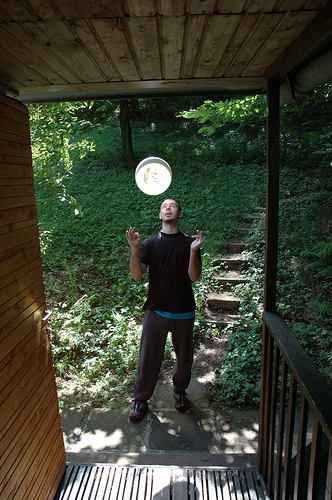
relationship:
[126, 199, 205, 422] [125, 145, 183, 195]
boy catching ball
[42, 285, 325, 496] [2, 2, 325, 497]
porch in front of house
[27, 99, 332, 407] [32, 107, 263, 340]
wooded area is outside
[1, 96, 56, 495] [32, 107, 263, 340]
wooded area is outside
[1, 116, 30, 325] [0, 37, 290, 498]
pine siding is on house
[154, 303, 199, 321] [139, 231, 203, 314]
blue shirt under shirt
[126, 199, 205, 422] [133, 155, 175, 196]
boy standing under pie pan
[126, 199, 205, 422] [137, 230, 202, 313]
boy wearing shirt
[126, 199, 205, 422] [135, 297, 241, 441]
boy wearing pants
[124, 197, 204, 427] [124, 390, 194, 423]
boy wearing tennis shoes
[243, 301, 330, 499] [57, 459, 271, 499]
fence on porch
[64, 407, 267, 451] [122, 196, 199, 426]
cement slabs under man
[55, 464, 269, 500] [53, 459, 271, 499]
slats on floor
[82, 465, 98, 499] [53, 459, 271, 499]
slats on floor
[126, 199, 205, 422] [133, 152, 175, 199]
boy throwing pan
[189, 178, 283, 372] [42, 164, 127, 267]
stairs leading to garden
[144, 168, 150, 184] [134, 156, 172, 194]
bird picture on pan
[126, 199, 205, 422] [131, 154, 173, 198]
boy looking at pan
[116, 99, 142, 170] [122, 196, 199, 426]
tree behind man